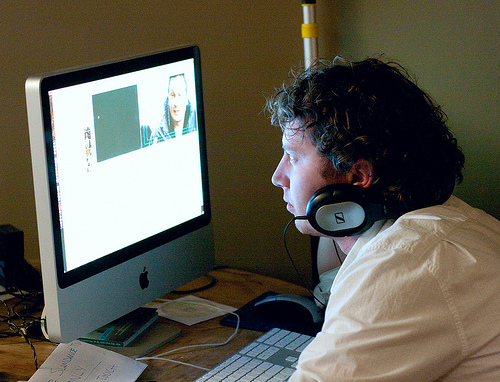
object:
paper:
[28, 339, 150, 381]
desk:
[0, 256, 315, 381]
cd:
[161, 299, 220, 318]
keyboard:
[190, 327, 318, 381]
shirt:
[286, 194, 499, 381]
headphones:
[305, 181, 377, 237]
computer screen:
[48, 56, 206, 274]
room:
[0, 0, 499, 381]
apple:
[138, 266, 151, 290]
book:
[75, 305, 162, 348]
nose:
[270, 152, 290, 190]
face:
[270, 113, 347, 237]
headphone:
[282, 183, 457, 309]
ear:
[346, 158, 374, 190]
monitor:
[25, 43, 217, 359]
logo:
[138, 265, 151, 291]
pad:
[218, 291, 328, 337]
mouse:
[252, 292, 325, 325]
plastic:
[300, 23, 321, 38]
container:
[0, 224, 43, 292]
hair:
[258, 53, 466, 203]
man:
[257, 51, 500, 381]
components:
[24, 42, 325, 381]